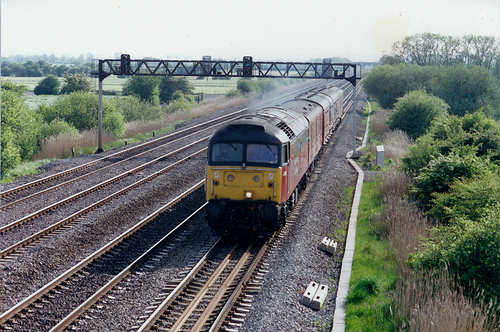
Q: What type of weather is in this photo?
A: It is clear.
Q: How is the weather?
A: It is clear.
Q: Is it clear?
A: Yes, it is clear.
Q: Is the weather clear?
A: Yes, it is clear.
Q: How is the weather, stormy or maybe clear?
A: It is clear.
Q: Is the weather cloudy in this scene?
A: No, it is clear.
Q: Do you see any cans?
A: No, there are no cans.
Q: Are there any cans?
A: No, there are no cans.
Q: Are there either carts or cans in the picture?
A: No, there are no cans or carts.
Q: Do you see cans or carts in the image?
A: No, there are no cans or carts.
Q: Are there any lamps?
A: No, there are no lamps.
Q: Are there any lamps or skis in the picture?
A: No, there are no lamps or skis.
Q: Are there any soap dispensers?
A: No, there are no soap dispensers.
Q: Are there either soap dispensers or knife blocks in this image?
A: No, there are no soap dispensers or knife blocks.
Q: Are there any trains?
A: Yes, there is a train.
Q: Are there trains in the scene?
A: Yes, there is a train.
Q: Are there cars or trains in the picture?
A: Yes, there is a train.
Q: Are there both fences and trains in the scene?
A: No, there is a train but no fences.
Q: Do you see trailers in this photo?
A: No, there are no trailers.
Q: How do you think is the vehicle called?
A: The vehicle is a train.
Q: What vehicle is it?
A: The vehicle is a train.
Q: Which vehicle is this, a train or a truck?
A: This is a train.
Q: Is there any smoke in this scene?
A: Yes, there is smoke.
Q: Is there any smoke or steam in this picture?
A: Yes, there is smoke.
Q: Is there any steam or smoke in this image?
A: Yes, there is smoke.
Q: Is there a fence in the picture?
A: No, there are no fences.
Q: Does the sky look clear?
A: Yes, the sky is clear.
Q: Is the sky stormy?
A: No, the sky is clear.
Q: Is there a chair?
A: No, there are no chairs.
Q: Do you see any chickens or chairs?
A: No, there are no chairs or chickens.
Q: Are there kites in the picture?
A: No, there are no kites.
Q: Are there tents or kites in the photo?
A: No, there are no kites or tents.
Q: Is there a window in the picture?
A: Yes, there is a window.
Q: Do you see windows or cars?
A: Yes, there is a window.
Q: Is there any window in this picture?
A: Yes, there is a window.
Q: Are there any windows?
A: Yes, there is a window.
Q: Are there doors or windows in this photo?
A: Yes, there is a window.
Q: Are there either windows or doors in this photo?
A: Yes, there is a window.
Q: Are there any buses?
A: No, there are no buses.